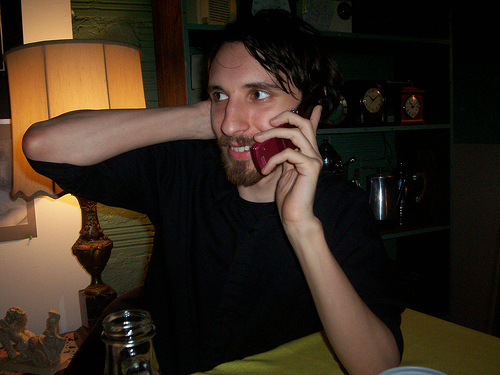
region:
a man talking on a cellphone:
[22, 24, 414, 368]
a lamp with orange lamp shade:
[2, 26, 147, 351]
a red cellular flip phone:
[241, 94, 316, 174]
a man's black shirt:
[22, 87, 412, 369]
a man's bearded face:
[202, 21, 308, 187]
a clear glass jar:
[95, 307, 161, 373]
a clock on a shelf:
[351, 78, 386, 127]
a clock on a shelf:
[395, 86, 427, 125]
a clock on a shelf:
[317, 73, 352, 133]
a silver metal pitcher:
[363, 161, 395, 231]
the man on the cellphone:
[14, 17, 449, 371]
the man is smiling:
[11, 15, 431, 361]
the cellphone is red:
[248, 101, 332, 191]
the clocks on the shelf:
[310, 75, 471, 140]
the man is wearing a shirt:
[25, 27, 412, 367]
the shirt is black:
[26, 30, 459, 370]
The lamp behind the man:
[5, 28, 178, 355]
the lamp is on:
[1, 35, 144, 330]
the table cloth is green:
[203, 303, 498, 373]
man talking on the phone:
[175, 11, 347, 199]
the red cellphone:
[249, 84, 332, 175]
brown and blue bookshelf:
[153, 1, 460, 316]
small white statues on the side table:
[0, 306, 70, 373]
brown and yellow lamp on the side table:
[2, 38, 154, 342]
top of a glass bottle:
[97, 307, 166, 374]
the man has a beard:
[207, 130, 269, 190]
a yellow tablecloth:
[187, 302, 498, 372]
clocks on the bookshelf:
[338, 71, 433, 131]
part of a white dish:
[372, 362, 447, 374]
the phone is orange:
[248, 130, 297, 165]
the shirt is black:
[149, 169, 351, 335]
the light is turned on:
[16, 49, 151, 167]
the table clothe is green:
[283, 338, 327, 373]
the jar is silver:
[368, 178, 399, 222]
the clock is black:
[351, 86, 389, 126]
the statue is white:
[6, 308, 71, 370]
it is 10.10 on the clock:
[358, 83, 385, 119]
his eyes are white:
[202, 76, 273, 106]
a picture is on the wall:
[0, 207, 41, 237]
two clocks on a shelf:
[357, 82, 425, 128]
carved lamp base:
[68, 192, 137, 357]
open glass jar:
[100, 308, 152, 374]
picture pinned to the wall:
[1, 124, 39, 242]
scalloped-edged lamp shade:
[3, 35, 149, 205]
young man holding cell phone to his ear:
[21, 20, 406, 372]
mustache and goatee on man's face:
[213, 133, 269, 188]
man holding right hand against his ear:
[20, 24, 407, 374]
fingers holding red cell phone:
[252, 101, 325, 176]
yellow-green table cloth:
[195, 304, 497, 374]